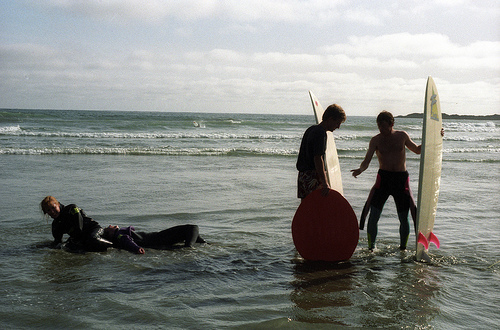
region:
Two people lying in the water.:
[39, 195, 210, 255]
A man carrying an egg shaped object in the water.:
[296, 98, 346, 202]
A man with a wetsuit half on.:
[350, 110, 446, 255]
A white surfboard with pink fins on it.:
[414, 74, 443, 261]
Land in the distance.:
[391, 111, 499, 121]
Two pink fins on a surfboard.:
[416, 231, 440, 252]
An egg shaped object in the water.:
[292, 187, 359, 267]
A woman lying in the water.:
[38, 193, 115, 252]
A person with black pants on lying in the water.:
[101, 223, 207, 254]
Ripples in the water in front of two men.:
[302, 261, 428, 326]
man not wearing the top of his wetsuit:
[365, 149, 433, 253]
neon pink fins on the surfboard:
[414, 233, 462, 268]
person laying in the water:
[31, 190, 177, 261]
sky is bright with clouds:
[28, 13, 495, 76]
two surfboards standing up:
[311, 78, 453, 298]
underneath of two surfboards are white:
[303, 75, 498, 217]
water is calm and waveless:
[108, 169, 255, 209]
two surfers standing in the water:
[273, 96, 430, 275]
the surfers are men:
[295, 88, 437, 248]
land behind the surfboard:
[403, 104, 498, 131]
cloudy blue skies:
[93, 32, 399, 96]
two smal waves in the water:
[68, 121, 234, 169]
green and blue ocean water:
[86, 157, 254, 198]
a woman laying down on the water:
[116, 205, 233, 266]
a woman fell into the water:
[30, 193, 114, 275]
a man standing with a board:
[276, 82, 350, 270]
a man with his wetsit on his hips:
[372, 108, 428, 283]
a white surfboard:
[424, 79, 450, 271]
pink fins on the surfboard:
[417, 231, 449, 258]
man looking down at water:
[273, 97, 348, 198]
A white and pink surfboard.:
[416, 75, 443, 259]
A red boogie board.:
[291, 186, 361, 265]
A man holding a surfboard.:
[349, 74, 446, 263]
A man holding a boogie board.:
[289, 102, 359, 264]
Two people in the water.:
[28, 197, 207, 256]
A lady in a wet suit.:
[31, 193, 112, 253]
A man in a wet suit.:
[100, 221, 207, 257]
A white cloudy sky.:
[1, 45, 496, 115]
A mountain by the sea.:
[395, 111, 499, 120]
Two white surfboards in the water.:
[308, 75, 442, 262]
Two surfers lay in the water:
[24, 182, 213, 274]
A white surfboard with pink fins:
[412, 70, 452, 272]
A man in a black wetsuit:
[356, 110, 428, 254]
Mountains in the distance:
[380, 107, 491, 121]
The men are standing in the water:
[286, 65, 455, 281]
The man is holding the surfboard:
[347, 62, 453, 265]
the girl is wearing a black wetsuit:
[35, 187, 115, 269]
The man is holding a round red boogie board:
[280, 86, 364, 271]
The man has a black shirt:
[289, 90, 352, 200]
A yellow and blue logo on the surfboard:
[421, 87, 451, 145]